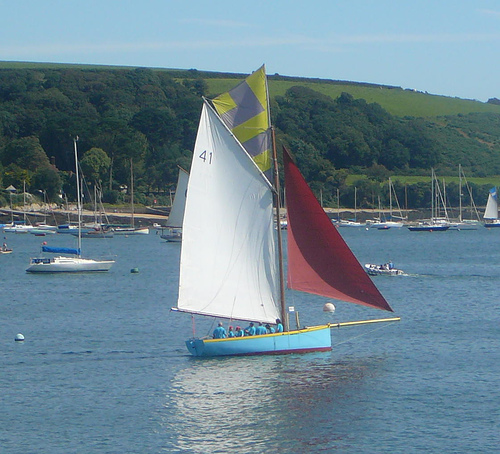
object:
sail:
[201, 67, 272, 170]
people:
[228, 328, 234, 337]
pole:
[78, 132, 82, 259]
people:
[236, 326, 246, 335]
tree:
[77, 145, 112, 202]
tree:
[116, 125, 148, 190]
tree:
[131, 110, 177, 146]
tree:
[32, 164, 64, 204]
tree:
[178, 117, 196, 138]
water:
[0, 217, 496, 452]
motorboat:
[364, 260, 406, 275]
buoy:
[322, 301, 333, 311]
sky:
[2, 3, 498, 103]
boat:
[173, 66, 403, 350]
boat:
[157, 162, 198, 242]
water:
[387, 307, 472, 417]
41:
[199, 149, 212, 166]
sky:
[375, 7, 431, 49]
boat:
[25, 129, 115, 272]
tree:
[381, 138, 411, 168]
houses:
[5, 185, 17, 204]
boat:
[406, 163, 451, 229]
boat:
[68, 129, 117, 237]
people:
[274, 319, 286, 330]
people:
[257, 321, 267, 336]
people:
[245, 321, 256, 335]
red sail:
[280, 147, 395, 312]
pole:
[270, 125, 285, 331]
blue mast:
[39, 244, 80, 254]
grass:
[177, 77, 499, 119]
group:
[209, 322, 226, 340]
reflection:
[167, 348, 384, 452]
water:
[0, 347, 499, 450]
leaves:
[137, 112, 174, 135]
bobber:
[14, 328, 28, 341]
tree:
[94, 90, 130, 137]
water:
[45, 319, 139, 414]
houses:
[401, 87, 413, 91]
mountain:
[5, 49, 496, 186]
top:
[2, 51, 492, 118]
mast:
[171, 98, 282, 324]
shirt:
[214, 329, 224, 336]